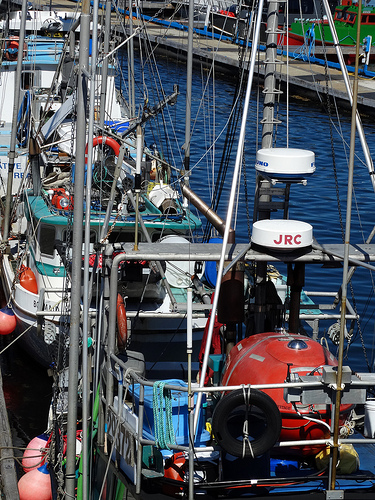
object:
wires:
[95, 0, 300, 232]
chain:
[45, 67, 77, 499]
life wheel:
[121, 175, 135, 192]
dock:
[0, 378, 20, 499]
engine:
[215, 329, 354, 463]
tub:
[128, 378, 207, 439]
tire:
[211, 387, 282, 460]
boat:
[16, 0, 375, 499]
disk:
[251, 219, 313, 256]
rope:
[153, 380, 175, 451]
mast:
[258, 23, 285, 211]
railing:
[100, 342, 375, 494]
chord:
[211, 388, 282, 460]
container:
[152, 379, 176, 451]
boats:
[0, 0, 375, 498]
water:
[111, 37, 375, 376]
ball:
[222, 330, 354, 460]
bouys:
[0, 0, 375, 499]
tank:
[17, 263, 38, 294]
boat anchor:
[17, 461, 52, 500]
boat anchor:
[22, 431, 50, 471]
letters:
[273, 234, 301, 244]